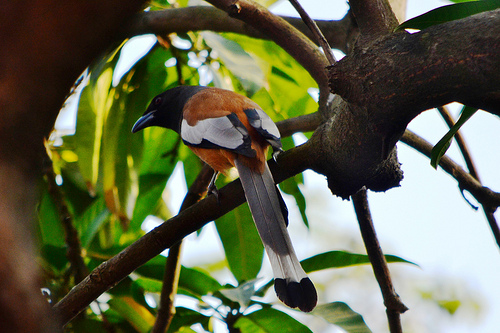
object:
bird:
[132, 83, 320, 310]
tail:
[234, 157, 318, 315]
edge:
[275, 275, 317, 312]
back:
[184, 86, 281, 157]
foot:
[194, 181, 224, 214]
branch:
[51, 150, 308, 321]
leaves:
[252, 250, 416, 297]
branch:
[248, 13, 498, 189]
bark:
[383, 34, 486, 81]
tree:
[0, 0, 500, 333]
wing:
[243, 101, 279, 155]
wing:
[243, 97, 283, 153]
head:
[134, 83, 189, 132]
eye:
[151, 97, 165, 109]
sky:
[49, 0, 500, 333]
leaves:
[202, 30, 263, 90]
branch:
[346, 174, 408, 333]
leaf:
[209, 168, 264, 285]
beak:
[130, 107, 157, 135]